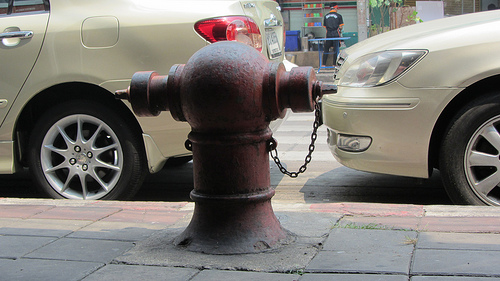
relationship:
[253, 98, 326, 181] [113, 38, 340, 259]
chain on hydrant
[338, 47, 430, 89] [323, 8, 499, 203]
headlight on car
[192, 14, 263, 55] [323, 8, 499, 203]
taillight on car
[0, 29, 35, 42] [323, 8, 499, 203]
handle on car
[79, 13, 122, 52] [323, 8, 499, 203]
tank door on car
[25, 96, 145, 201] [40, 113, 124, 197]
tire on wheel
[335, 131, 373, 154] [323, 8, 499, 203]
light on car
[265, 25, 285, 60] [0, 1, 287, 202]
plate on car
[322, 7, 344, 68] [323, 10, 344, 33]
man wearing shirt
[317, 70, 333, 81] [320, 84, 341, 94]
block in sidewalk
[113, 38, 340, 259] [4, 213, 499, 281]
hydrant on sidewalk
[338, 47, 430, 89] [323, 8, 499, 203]
headlight on vehicle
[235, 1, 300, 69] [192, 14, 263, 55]
rear tail taillight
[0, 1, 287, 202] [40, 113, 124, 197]
vehicle rear wheel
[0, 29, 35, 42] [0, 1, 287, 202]
handle on vehicle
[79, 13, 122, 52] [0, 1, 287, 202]
cover on vehicle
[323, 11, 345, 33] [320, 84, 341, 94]
man on sidewalk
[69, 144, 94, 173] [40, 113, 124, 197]
nuts on wheel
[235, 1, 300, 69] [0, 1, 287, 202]
rear plate on vehicle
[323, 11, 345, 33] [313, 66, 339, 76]
man stands on street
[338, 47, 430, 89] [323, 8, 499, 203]
headlight of car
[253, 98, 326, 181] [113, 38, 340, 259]
chain attached to hydrant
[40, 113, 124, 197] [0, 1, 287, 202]
rear wheel of vehicle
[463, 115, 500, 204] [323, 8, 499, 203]
wheel of vehicle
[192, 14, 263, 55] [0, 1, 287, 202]
taillight of car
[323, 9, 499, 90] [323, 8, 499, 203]
hood of automobile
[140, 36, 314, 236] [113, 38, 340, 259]
weathered fire hydrant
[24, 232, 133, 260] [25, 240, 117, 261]
individual paving stone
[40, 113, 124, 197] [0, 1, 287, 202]
wheel of a car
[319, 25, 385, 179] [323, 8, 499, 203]
head of car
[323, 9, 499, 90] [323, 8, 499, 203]
hood of car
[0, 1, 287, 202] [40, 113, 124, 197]
car rear wheel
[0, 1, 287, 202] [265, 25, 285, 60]
car license plate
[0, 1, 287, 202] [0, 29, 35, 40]
car door handle